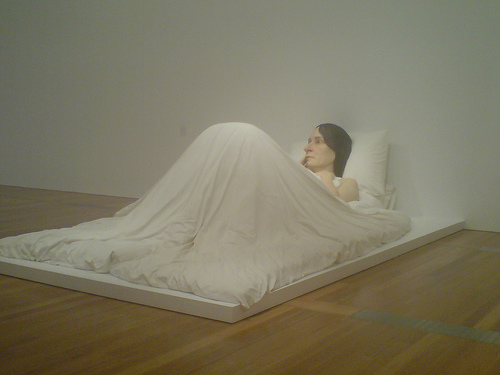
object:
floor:
[0, 228, 499, 375]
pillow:
[283, 129, 391, 197]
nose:
[302, 144, 314, 153]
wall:
[2, 0, 498, 234]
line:
[292, 296, 499, 344]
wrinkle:
[147, 122, 250, 231]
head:
[303, 123, 351, 168]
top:
[306, 123, 342, 136]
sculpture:
[167, 122, 359, 221]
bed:
[0, 209, 467, 322]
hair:
[315, 123, 353, 179]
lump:
[137, 123, 345, 259]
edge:
[0, 256, 236, 324]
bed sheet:
[1, 121, 409, 311]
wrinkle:
[116, 120, 256, 237]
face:
[304, 125, 337, 168]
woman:
[295, 123, 359, 206]